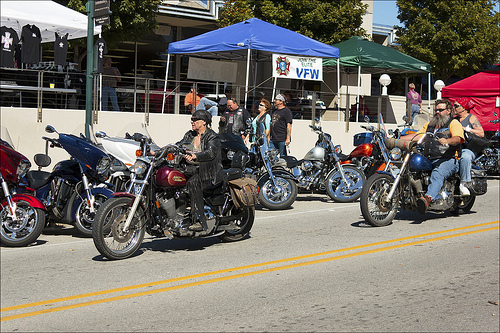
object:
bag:
[228, 177, 259, 208]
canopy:
[324, 36, 432, 73]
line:
[0, 222, 497, 324]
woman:
[453, 95, 486, 202]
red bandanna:
[455, 97, 474, 110]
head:
[453, 101, 464, 113]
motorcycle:
[279, 117, 365, 202]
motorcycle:
[257, 169, 299, 210]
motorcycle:
[81, 130, 164, 177]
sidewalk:
[0, 196, 500, 317]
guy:
[173, 110, 222, 231]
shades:
[260, 104, 264, 106]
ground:
[0, 237, 500, 333]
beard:
[429, 113, 450, 126]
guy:
[413, 100, 466, 213]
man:
[452, 101, 486, 197]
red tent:
[442, 72, 499, 135]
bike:
[359, 115, 487, 227]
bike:
[27, 124, 121, 237]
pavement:
[3, 260, 500, 332]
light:
[134, 159, 148, 174]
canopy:
[164, 18, 340, 59]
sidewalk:
[0, 102, 411, 172]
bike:
[93, 131, 257, 261]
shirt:
[54, 32, 69, 66]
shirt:
[20, 24, 42, 64]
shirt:
[0, 26, 20, 69]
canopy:
[0, 0, 103, 43]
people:
[218, 99, 251, 140]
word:
[298, 57, 317, 67]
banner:
[271, 52, 324, 82]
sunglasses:
[191, 117, 206, 122]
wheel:
[91, 197, 146, 261]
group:
[90, 82, 483, 261]